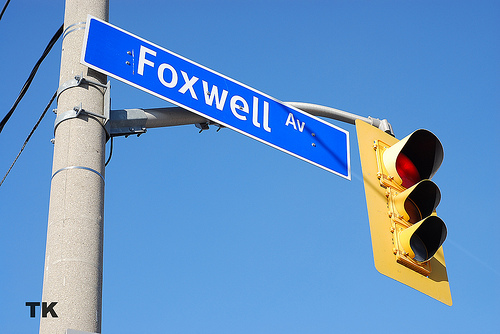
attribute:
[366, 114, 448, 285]
street light — red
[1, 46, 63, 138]
wires — utility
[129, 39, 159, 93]
letter — white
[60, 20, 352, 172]
sign — blue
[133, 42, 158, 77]
letter — white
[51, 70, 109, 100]
brackets — support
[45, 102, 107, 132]
brackets — support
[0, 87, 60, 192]
power cable — black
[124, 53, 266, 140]
letter — white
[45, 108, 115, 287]
pole — steel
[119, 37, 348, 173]
sign — street name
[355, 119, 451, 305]
traffic light — yellow framed, red, lit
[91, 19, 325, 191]
sign — blue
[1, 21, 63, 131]
cable — black 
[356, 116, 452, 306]
stop light — yellow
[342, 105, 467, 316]
traffic signal — Metal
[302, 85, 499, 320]
traffic signal — metal, yellow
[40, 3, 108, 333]
pole — metal